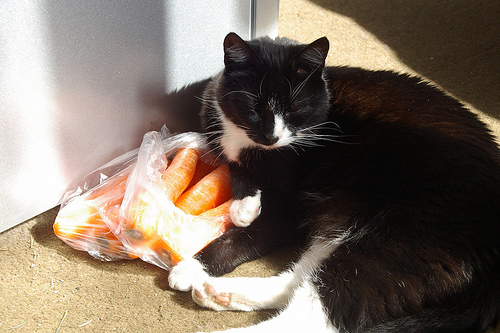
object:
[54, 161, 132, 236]
carrot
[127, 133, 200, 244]
carrot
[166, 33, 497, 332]
cat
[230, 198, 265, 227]
paws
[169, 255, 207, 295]
paw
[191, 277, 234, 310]
paw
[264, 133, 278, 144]
nose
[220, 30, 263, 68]
ear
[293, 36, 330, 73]
ear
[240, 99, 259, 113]
eye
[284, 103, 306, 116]
eye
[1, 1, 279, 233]
fridge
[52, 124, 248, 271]
bag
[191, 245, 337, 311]
leg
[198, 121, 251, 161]
whiskers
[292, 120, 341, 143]
whiskers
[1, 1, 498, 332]
floor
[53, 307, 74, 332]
twig